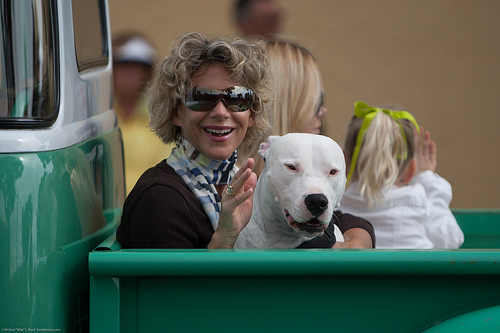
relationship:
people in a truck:
[125, 39, 439, 239] [3, 0, 499, 329]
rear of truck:
[90, 198, 500, 330] [3, 0, 499, 329]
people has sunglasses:
[108, 29, 376, 254] [182, 89, 257, 109]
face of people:
[175, 63, 255, 155] [108, 29, 376, 254]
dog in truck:
[241, 134, 355, 251] [3, 0, 499, 329]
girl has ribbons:
[341, 100, 471, 257] [345, 103, 425, 185]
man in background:
[232, 4, 299, 37] [73, 4, 499, 187]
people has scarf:
[108, 29, 376, 254] [169, 136, 246, 225]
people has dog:
[108, 29, 376, 254] [241, 134, 355, 251]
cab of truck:
[3, 1, 128, 332] [3, 0, 499, 329]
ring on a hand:
[224, 183, 239, 197] [212, 159, 255, 248]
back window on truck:
[68, 0, 114, 79] [3, 0, 499, 329]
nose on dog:
[305, 194, 327, 218] [241, 134, 355, 251]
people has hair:
[108, 29, 376, 254] [145, 41, 272, 141]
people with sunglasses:
[108, 29, 376, 254] [182, 89, 257, 109]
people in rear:
[125, 39, 439, 239] [90, 198, 500, 330]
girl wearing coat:
[341, 100, 471, 257] [348, 173, 467, 252]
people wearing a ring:
[108, 29, 376, 254] [228, 183, 236, 197]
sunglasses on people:
[182, 89, 257, 109] [108, 29, 376, 254]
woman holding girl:
[241, 36, 336, 142] [341, 100, 471, 257]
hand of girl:
[414, 127, 439, 178] [341, 100, 471, 257]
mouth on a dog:
[279, 203, 333, 236] [241, 134, 355, 251]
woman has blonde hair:
[241, 36, 336, 142] [259, 38, 319, 131]